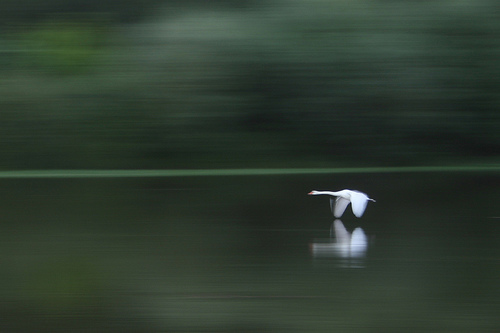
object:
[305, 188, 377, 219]
bird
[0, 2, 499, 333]
water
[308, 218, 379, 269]
reflection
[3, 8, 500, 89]
background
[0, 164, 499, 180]
line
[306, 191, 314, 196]
beak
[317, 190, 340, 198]
neck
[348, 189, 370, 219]
wing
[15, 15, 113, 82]
leaves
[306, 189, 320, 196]
head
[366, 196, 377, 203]
tail